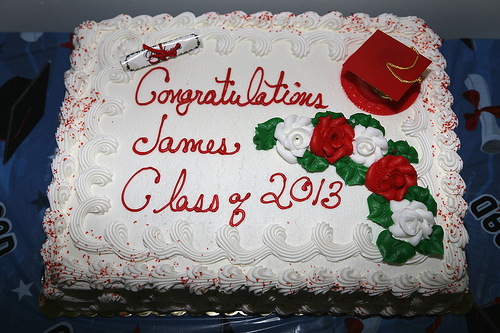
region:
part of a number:
[248, 152, 280, 223]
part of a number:
[291, 171, 316, 203]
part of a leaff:
[375, 228, 401, 257]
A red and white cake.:
[40, 9, 470, 318]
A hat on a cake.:
[339, 28, 433, 117]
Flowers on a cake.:
[253, 109, 445, 265]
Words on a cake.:
[120, 66, 343, 226]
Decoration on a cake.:
[119, 31, 201, 73]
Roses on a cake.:
[273, 113, 435, 248]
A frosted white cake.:
[38, 8, 470, 320]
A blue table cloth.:
[3, 28, 495, 330]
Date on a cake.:
[261, 172, 344, 209]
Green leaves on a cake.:
[252, 110, 445, 266]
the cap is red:
[351, 29, 414, 117]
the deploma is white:
[124, 40, 196, 60]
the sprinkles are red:
[87, 261, 129, 286]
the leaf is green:
[379, 231, 409, 268]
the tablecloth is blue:
[10, 158, 35, 184]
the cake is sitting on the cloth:
[25, 211, 88, 321]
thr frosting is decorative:
[261, 224, 308, 258]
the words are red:
[128, 166, 203, 218]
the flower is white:
[273, 114, 310, 169]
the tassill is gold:
[382, 53, 414, 85]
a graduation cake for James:
[26, 7, 496, 321]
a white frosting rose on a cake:
[383, 198, 435, 253]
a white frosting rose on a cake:
[348, 118, 389, 172]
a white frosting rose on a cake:
[273, 111, 316, 167]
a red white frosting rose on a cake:
[313, 111, 353, 166]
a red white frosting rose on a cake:
[366, 153, 418, 201]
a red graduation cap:
[341, 29, 432, 108]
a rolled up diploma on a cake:
[117, 26, 206, 76]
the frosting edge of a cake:
[106, 218, 270, 269]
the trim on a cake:
[55, 257, 447, 307]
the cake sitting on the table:
[46, 14, 467, 319]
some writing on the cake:
[124, 68, 346, 225]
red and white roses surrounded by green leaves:
[261, 108, 434, 262]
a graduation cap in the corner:
[336, 23, 420, 111]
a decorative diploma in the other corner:
[118, 25, 197, 72]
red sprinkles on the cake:
[28, 205, 107, 295]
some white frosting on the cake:
[212, 25, 349, 69]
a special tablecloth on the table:
[439, 17, 494, 272]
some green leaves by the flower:
[369, 196, 407, 266]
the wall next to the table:
[0, 1, 493, 32]